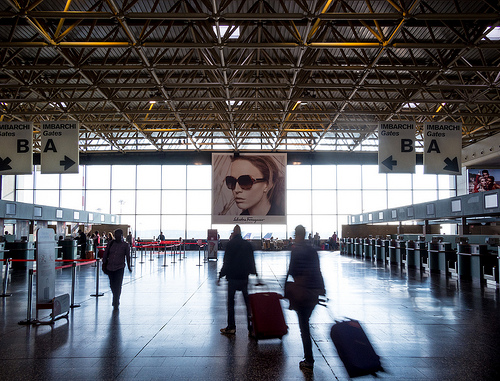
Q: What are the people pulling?
A: Suitcases.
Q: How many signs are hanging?
A: Five.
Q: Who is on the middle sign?
A: A woman.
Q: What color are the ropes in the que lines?
A: Red.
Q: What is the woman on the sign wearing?
A: Sunglasses.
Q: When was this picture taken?
A: Daytime.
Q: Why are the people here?
A: Traveling.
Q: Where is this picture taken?
A: Airport.